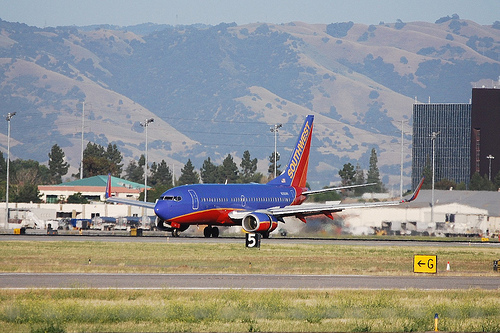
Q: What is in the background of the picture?
A: Mountains.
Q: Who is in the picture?
A: No one.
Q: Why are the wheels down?
A: To move.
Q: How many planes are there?
A: 1.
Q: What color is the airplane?
A: Blue and red.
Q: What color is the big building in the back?
A: Black.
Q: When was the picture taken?
A: Daytime.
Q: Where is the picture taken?
A: Airport.